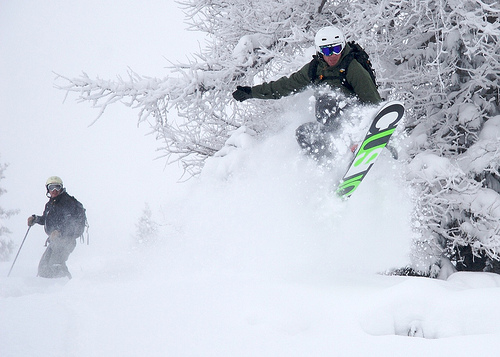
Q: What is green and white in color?
A: Skateboard.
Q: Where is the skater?
A: In the air.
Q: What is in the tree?
A: Snow.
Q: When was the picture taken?
A: Winter season.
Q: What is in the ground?
A: Snow.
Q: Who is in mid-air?
A: A snowboarder.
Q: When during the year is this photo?
A: Winter.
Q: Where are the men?
A: In snow.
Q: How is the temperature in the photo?
A: Cold.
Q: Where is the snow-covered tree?
A: To the right.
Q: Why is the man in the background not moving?
A: Resting.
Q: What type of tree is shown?
A: Pine.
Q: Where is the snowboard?
A: ON the man's feet.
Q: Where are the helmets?
A: On the people's heads.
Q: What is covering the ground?
A: Snow.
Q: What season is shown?
A: Winter.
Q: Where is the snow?
A: On the ground.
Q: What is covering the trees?
A: Snow.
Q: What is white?
A: The snow.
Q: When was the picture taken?
A: Daytime.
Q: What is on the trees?
A: Snow.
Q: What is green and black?
A: A snowboard.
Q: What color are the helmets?
A: White.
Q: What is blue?
A: Goggles.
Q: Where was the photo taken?
A: At a ski resort.